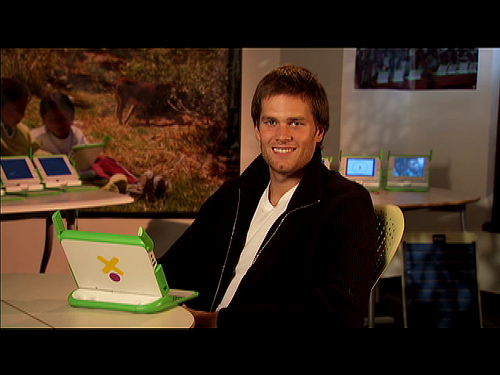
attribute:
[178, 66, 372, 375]
man — smiling, sitting, grown, confused, posing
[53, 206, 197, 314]
laptop — sitting, white, green, new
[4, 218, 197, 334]
table — tan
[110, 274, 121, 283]
dot — red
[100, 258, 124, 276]
x — yellow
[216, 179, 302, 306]
shirt — white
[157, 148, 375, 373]
jacket — black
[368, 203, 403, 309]
chair — tan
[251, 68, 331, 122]
hair — brown, short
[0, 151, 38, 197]
laptop — off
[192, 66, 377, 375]
tom brady — here, smiling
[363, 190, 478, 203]
table — round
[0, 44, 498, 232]
walls — white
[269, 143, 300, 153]
smile — beautiful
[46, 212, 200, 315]
tablet — white, green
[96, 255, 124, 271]
cross — yellow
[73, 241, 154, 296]
cover — white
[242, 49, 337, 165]
wall — small, white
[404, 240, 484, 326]
bin — blue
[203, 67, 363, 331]
hunk — sitting, gorgeous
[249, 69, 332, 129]
haircut — bowled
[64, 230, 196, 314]
computer — plastic